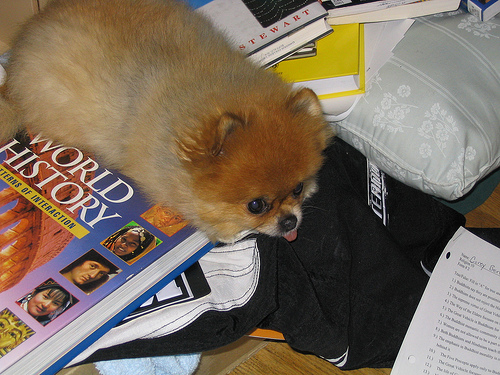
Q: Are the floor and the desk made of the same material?
A: Yes, both the floor and the desk are made of wood.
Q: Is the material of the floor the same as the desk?
A: Yes, both the floor and the desk are made of wood.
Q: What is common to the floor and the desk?
A: The material, both the floor and the desk are wooden.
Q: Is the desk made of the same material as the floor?
A: Yes, both the desk and the floor are made of wood.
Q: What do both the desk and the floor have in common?
A: The material, both the desk and the floor are wooden.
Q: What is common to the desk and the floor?
A: The material, both the desk and the floor are wooden.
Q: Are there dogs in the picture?
A: Yes, there is a dog.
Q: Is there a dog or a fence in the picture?
A: Yes, there is a dog.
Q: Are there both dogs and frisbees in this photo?
A: No, there is a dog but no frisbees.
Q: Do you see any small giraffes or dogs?
A: Yes, there is a small dog.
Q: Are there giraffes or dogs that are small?
A: Yes, the dog is small.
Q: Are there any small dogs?
A: Yes, there is a small dog.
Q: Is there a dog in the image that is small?
A: Yes, there is a dog that is small.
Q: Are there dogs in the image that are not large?
A: Yes, there is a small dog.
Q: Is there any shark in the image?
A: No, there are no sharks.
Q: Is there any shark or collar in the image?
A: No, there are no sharks or collars.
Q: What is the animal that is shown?
A: The animal is a dog.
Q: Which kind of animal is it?
A: The animal is a dog.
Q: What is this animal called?
A: This is a dog.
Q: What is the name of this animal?
A: This is a dog.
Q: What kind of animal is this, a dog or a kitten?
A: This is a dog.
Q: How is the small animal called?
A: The animal is a dog.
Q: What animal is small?
A: The animal is a dog.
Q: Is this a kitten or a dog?
A: This is a dog.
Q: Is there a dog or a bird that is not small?
A: No, there is a dog but it is small.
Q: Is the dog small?
A: Yes, the dog is small.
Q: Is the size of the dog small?
A: Yes, the dog is small.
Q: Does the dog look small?
A: Yes, the dog is small.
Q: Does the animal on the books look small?
A: Yes, the dog is small.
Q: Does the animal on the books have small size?
A: Yes, the dog is small.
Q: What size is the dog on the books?
A: The dog is small.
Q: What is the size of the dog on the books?
A: The dog is small.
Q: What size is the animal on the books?
A: The dog is small.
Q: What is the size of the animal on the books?
A: The dog is small.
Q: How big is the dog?
A: The dog is small.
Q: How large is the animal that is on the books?
A: The dog is small.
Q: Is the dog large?
A: No, the dog is small.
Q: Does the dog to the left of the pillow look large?
A: No, the dog is small.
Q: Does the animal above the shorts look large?
A: No, the dog is small.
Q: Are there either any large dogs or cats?
A: No, there is a dog but it is small.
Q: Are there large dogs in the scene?
A: No, there is a dog but it is small.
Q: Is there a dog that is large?
A: No, there is a dog but it is small.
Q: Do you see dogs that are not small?
A: No, there is a dog but it is small.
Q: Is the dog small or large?
A: The dog is small.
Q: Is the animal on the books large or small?
A: The dog is small.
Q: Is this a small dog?
A: Yes, this is a small dog.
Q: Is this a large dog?
A: No, this is a small dog.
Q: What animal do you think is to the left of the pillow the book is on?
A: The animal is a dog.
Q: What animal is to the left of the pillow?
A: The animal is a dog.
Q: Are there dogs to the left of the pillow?
A: Yes, there is a dog to the left of the pillow.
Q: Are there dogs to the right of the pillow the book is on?
A: No, the dog is to the left of the pillow.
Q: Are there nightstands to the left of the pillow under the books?
A: No, there is a dog to the left of the pillow.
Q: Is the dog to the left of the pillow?
A: Yes, the dog is to the left of the pillow.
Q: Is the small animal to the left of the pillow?
A: Yes, the dog is to the left of the pillow.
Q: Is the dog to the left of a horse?
A: No, the dog is to the left of the pillow.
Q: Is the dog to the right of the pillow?
A: No, the dog is to the left of the pillow.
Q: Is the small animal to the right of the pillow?
A: No, the dog is to the left of the pillow.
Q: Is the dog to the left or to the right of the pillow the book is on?
A: The dog is to the left of the pillow.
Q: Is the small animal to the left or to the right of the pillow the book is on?
A: The dog is to the left of the pillow.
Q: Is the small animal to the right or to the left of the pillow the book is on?
A: The dog is to the left of the pillow.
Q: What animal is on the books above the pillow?
A: The dog is on the books.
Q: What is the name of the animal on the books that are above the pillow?
A: The animal is a dog.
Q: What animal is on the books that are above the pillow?
A: The animal is a dog.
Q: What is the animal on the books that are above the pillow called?
A: The animal is a dog.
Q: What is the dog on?
A: The dog is on the books.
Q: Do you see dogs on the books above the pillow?
A: Yes, there is a dog on the books.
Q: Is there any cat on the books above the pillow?
A: No, there is a dog on the books.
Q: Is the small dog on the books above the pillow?
A: Yes, the dog is on the books.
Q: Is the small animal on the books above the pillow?
A: Yes, the dog is on the books.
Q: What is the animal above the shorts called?
A: The animal is a dog.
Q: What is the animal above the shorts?
A: The animal is a dog.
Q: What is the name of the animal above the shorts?
A: The animal is a dog.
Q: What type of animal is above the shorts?
A: The animal is a dog.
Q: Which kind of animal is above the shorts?
A: The animal is a dog.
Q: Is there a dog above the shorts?
A: Yes, there is a dog above the shorts.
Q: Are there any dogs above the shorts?
A: Yes, there is a dog above the shorts.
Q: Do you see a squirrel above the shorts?
A: No, there is a dog above the shorts.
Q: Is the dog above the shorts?
A: Yes, the dog is above the shorts.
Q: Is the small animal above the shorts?
A: Yes, the dog is above the shorts.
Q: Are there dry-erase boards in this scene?
A: No, there are no dry-erase boards.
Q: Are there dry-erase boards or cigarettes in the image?
A: No, there are no dry-erase boards or cigarettes.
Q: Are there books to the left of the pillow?
A: Yes, there is a book to the left of the pillow.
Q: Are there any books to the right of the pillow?
A: No, the book is to the left of the pillow.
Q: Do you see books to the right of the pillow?
A: No, the book is to the left of the pillow.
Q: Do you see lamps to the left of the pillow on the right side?
A: No, there is a book to the left of the pillow.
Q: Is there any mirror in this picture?
A: No, there are no mirrors.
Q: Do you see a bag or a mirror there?
A: No, there are no mirrors or bags.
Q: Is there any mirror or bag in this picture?
A: No, there are no mirrors or bags.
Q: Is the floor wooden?
A: Yes, the floor is wooden.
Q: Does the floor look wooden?
A: Yes, the floor is wooden.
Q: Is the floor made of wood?
A: Yes, the floor is made of wood.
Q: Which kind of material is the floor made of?
A: The floor is made of wood.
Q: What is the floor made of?
A: The floor is made of wood.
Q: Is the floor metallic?
A: No, the floor is wooden.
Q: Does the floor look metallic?
A: No, the floor is wooden.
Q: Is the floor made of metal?
A: No, the floor is made of wood.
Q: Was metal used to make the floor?
A: No, the floor is made of wood.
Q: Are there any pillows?
A: Yes, there is a pillow.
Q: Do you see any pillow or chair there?
A: Yes, there is a pillow.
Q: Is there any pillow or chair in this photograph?
A: Yes, there is a pillow.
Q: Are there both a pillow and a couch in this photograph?
A: No, there is a pillow but no couches.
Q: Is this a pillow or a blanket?
A: This is a pillow.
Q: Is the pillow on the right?
A: Yes, the pillow is on the right of the image.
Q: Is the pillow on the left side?
A: No, the pillow is on the right of the image.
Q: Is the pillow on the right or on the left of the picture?
A: The pillow is on the right of the image.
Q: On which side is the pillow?
A: The pillow is on the right of the image.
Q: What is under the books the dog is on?
A: The pillow is under the books.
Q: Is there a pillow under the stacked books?
A: Yes, there is a pillow under the books.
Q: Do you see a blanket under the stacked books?
A: No, there is a pillow under the books.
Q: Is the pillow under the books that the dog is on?
A: Yes, the pillow is under the books.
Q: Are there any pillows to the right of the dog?
A: Yes, there is a pillow to the right of the dog.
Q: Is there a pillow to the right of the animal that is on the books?
A: Yes, there is a pillow to the right of the dog.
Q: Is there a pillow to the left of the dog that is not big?
A: No, the pillow is to the right of the dog.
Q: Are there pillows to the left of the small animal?
A: No, the pillow is to the right of the dog.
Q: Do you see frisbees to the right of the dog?
A: No, there is a pillow to the right of the dog.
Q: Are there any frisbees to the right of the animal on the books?
A: No, there is a pillow to the right of the dog.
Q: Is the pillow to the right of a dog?
A: Yes, the pillow is to the right of a dog.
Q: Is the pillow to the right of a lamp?
A: No, the pillow is to the right of a dog.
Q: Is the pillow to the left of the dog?
A: No, the pillow is to the right of the dog.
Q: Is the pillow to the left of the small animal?
A: No, the pillow is to the right of the dog.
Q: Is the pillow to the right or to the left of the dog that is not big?
A: The pillow is to the right of the dog.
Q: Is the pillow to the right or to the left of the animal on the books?
A: The pillow is to the right of the dog.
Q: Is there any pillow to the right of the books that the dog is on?
A: Yes, there is a pillow to the right of the books.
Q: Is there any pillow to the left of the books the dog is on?
A: No, the pillow is to the right of the books.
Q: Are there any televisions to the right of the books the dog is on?
A: No, there is a pillow to the right of the books.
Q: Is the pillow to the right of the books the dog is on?
A: Yes, the pillow is to the right of the books.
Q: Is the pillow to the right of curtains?
A: No, the pillow is to the right of the books.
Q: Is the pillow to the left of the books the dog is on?
A: No, the pillow is to the right of the books.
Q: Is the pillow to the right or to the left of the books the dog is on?
A: The pillow is to the right of the books.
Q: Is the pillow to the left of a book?
A: No, the pillow is to the right of a book.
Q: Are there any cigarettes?
A: No, there are no cigarettes.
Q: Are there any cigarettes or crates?
A: No, there are no cigarettes or crates.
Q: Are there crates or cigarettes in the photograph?
A: No, there are no cigarettes or crates.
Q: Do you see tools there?
A: No, there are no tools.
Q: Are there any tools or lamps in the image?
A: No, there are no tools or lamps.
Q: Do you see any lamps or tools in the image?
A: No, there are no tools or lamps.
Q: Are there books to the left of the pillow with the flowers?
A: Yes, there are books to the left of the pillow.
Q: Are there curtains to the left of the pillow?
A: No, there are books to the left of the pillow.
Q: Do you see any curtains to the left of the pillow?
A: No, there are books to the left of the pillow.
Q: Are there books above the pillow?
A: Yes, there are books above the pillow.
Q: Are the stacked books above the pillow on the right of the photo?
A: Yes, the books are above the pillow.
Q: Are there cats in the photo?
A: No, there are no cats.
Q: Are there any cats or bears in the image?
A: No, there are no cats or bears.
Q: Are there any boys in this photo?
A: No, there are no boys.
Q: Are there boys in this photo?
A: No, there are no boys.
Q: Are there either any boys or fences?
A: No, there are no boys or fences.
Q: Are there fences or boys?
A: No, there are no boys or fences.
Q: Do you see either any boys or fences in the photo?
A: No, there are no boys or fences.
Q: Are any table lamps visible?
A: No, there are no table lamps.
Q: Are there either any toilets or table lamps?
A: No, there are no table lamps or toilets.